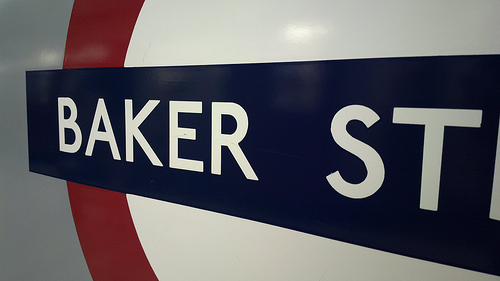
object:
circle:
[61, 0, 157, 281]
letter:
[58, 97, 82, 153]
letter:
[390, 107, 481, 212]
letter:
[211, 102, 258, 180]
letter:
[168, 102, 203, 174]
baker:
[57, 97, 259, 181]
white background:
[0, 0, 500, 281]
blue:
[24, 54, 499, 275]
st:
[326, 104, 481, 211]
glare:
[38, 20, 322, 111]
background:
[58, 98, 482, 213]